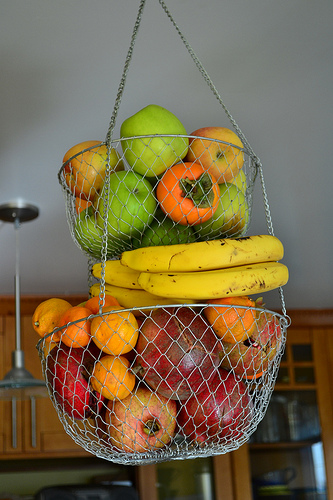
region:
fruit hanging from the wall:
[29, 76, 295, 467]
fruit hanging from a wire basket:
[22, 75, 324, 493]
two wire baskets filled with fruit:
[22, 127, 330, 479]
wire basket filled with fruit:
[49, 109, 290, 266]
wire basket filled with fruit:
[28, 284, 332, 483]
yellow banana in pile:
[120, 239, 282, 294]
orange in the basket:
[86, 312, 137, 360]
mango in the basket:
[140, 311, 218, 401]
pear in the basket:
[98, 175, 150, 243]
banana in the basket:
[119, 232, 286, 282]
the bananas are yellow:
[83, 243, 297, 301]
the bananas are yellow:
[88, 238, 308, 325]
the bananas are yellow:
[85, 231, 291, 312]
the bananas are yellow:
[90, 227, 294, 315]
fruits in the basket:
[38, 273, 300, 488]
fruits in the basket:
[20, 280, 265, 452]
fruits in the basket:
[23, 300, 292, 481]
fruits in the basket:
[18, 292, 261, 469]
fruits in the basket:
[35, 304, 264, 466]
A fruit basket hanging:
[49, 109, 315, 476]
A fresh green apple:
[116, 100, 177, 167]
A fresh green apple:
[95, 178, 151, 234]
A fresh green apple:
[78, 214, 119, 259]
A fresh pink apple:
[191, 127, 246, 177]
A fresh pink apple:
[59, 137, 105, 199]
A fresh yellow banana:
[138, 262, 289, 300]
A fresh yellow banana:
[119, 243, 281, 268]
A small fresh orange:
[90, 357, 144, 419]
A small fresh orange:
[89, 313, 136, 348]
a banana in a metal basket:
[117, 234, 286, 273]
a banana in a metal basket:
[130, 262, 287, 300]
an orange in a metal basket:
[89, 301, 137, 357]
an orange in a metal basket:
[57, 304, 94, 350]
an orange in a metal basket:
[29, 296, 76, 341]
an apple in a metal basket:
[120, 102, 189, 178]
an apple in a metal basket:
[101, 170, 155, 234]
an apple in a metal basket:
[76, 199, 126, 257]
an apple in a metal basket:
[59, 137, 126, 201]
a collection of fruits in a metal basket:
[32, 103, 291, 466]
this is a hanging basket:
[18, 3, 296, 463]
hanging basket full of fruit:
[49, 97, 307, 484]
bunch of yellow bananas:
[89, 231, 296, 306]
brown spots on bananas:
[213, 230, 250, 251]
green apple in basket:
[82, 161, 161, 229]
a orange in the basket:
[150, 153, 221, 221]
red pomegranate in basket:
[129, 299, 222, 392]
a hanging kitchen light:
[1, 189, 43, 423]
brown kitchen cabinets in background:
[4, 273, 116, 460]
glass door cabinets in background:
[236, 326, 317, 498]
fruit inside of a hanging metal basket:
[29, 0, 291, 469]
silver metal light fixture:
[0, 200, 48, 388]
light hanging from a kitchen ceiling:
[1, 199, 46, 389]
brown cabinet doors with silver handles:
[0, 313, 96, 451]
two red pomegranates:
[131, 305, 250, 445]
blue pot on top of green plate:
[252, 465, 296, 490]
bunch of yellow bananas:
[86, 233, 288, 316]